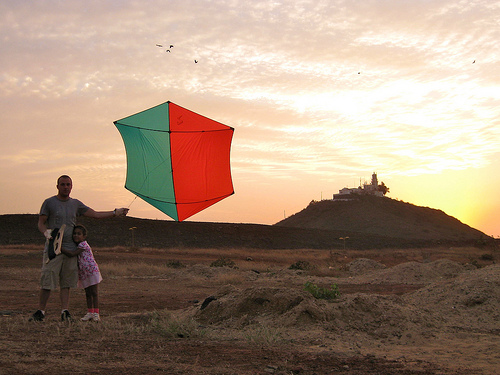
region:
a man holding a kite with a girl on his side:
[28, 100, 235, 322]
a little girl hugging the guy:
[28, 174, 102, 324]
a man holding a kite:
[31, 99, 234, 239]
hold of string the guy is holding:
[44, 223, 63, 263]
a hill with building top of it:
[275, 169, 495, 244]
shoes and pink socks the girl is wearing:
[81, 305, 101, 321]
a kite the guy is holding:
[113, 100, 235, 222]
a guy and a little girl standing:
[26, 173, 103, 324]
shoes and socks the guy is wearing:
[28, 308, 72, 323]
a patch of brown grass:
[154, 313, 186, 334]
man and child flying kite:
[35, 97, 238, 325]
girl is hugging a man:
[30, 174, 129, 323]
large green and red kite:
[111, 98, 236, 225]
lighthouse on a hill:
[366, 168, 383, 195]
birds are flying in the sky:
[154, 42, 199, 66]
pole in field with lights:
[126, 222, 138, 251]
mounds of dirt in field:
[200, 255, 493, 352]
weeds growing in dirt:
[302, 278, 344, 303]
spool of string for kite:
[43, 223, 68, 265]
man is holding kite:
[37, 100, 237, 320]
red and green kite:
[103, 99, 230, 223]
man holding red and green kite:
[35, 171, 143, 322]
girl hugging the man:
[62, 230, 107, 327]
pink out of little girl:
[70, 247, 103, 287]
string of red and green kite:
[128, 169, 158, 222]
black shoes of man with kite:
[23, 310, 74, 324]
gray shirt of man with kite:
[45, 193, 85, 253]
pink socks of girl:
[81, 306, 101, 313]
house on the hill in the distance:
[330, 175, 391, 198]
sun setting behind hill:
[268, 182, 498, 247]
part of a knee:
[84, 268, 118, 310]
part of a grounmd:
[221, 349, 246, 374]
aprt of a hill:
[259, 275, 278, 308]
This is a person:
[33, 172, 133, 328]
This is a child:
[69, 219, 112, 329]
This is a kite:
[109, 94, 263, 239]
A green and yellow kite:
[98, 82, 264, 229]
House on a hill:
[316, 149, 412, 203]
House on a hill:
[312, 168, 435, 248]